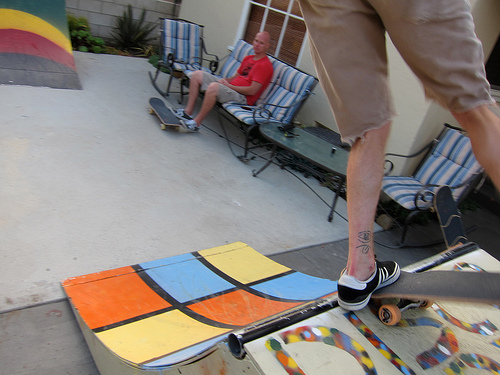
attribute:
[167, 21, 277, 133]
man — bald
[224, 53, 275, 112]
shirt — red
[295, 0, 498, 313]
man — skateboarding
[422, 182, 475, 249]
skateboard — black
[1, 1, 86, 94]
skateboard ramp — rainbow design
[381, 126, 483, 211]
cushion — blue, white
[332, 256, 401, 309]
sneaker — black, white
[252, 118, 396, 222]
coffee table — outdoors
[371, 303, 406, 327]
skateboard wheel — orange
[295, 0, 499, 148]
shorts — brown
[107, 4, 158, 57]
plant — green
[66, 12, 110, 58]
plant — green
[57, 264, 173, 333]
square — orange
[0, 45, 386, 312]
concrete — grey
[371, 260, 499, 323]
skateboard — tilted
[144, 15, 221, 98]
rocking chair — blue, white